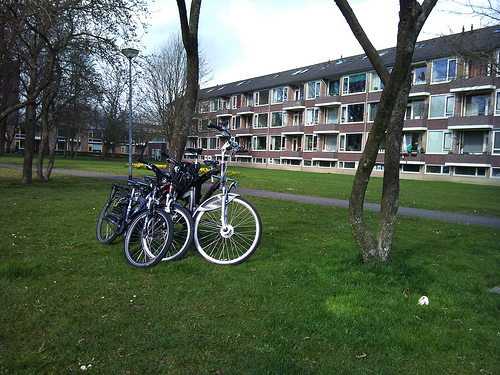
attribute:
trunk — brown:
[335, 0, 441, 277]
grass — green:
[3, 157, 497, 371]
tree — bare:
[3, 0, 128, 185]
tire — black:
[194, 180, 276, 272]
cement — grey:
[245, 182, 498, 242]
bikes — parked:
[88, 113, 273, 272]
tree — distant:
[1, 0, 152, 184]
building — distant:
[231, 66, 383, 183]